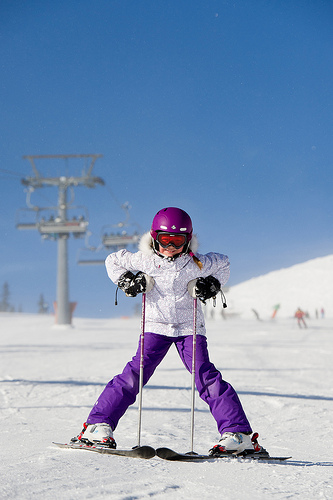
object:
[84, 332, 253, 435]
snowpants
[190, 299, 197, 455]
poles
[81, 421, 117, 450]
shoes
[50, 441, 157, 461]
skis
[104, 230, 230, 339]
jacket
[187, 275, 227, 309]
gloves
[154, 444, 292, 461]
board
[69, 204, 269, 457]
girl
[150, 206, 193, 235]
helmet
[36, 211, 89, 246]
ski lift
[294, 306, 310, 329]
people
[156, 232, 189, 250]
goggles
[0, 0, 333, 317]
sky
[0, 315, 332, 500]
ground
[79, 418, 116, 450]
foot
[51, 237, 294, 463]
outfit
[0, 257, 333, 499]
snow